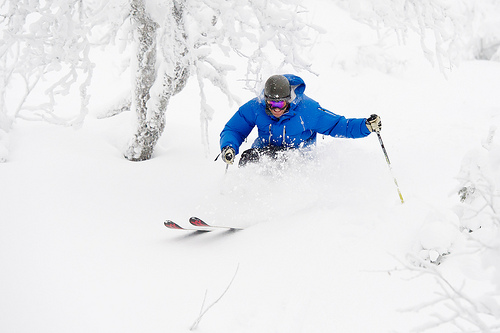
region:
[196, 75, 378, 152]
the blue snow jacket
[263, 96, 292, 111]
the iridescent snow goggles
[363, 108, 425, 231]
the left ski pole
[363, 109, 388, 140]
the gloves on the left hand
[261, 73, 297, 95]
the hat of the skier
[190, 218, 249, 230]
the left ski of the skier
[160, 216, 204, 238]
the right ski of the skier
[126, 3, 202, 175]
the snow covered tree trunk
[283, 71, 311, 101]
the hood of the blue jacket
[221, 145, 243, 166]
the right glove of the skier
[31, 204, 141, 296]
ground covered in white snow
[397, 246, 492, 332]
tree branches covered in snow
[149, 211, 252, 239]
red and black skis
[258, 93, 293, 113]
pair of purple safety goggles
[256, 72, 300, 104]
black safety helmet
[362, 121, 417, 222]
black and yellow ski pole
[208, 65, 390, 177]
man in blue jacket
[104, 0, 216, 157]
tree covered in snow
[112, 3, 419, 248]
man skiing in snow covered forest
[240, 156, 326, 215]
snow cloud flying in air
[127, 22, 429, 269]
a person skiing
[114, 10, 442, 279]
a person in blue snow coat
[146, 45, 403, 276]
a person in blue coat skiing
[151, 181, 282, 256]
a partially seen skis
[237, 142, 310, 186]
a partially visible black pants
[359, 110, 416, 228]
a ski pole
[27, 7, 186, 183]
trees covered with snow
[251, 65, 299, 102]
a black helmet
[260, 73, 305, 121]
a person wearing a google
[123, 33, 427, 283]
a skier in motion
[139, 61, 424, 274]
a person skiing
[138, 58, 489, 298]
a person skiingin snow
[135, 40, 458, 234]
a person surround by snow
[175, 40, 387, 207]
a person wearing a helmet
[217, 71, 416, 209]
a person wearing a black helmet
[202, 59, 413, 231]
a person wearing a jacket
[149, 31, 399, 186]
a person wearing a blue jacket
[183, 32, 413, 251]
a person holding ski poles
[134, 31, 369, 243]
a person on skies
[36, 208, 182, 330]
ground covered in snow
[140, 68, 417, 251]
a man riding skis down a snow covered slope.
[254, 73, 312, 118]
a man wearing a helmet.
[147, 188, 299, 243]
skis flying through snow.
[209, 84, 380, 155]
a blue puffy jacket.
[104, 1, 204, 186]
a tree covered in snow.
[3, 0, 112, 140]
snow covered tree branches.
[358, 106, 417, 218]
a ski pole in snow.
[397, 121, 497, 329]
snow drenched tree branches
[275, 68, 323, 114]
a hood on a jacket.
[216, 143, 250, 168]
a glove on a left hand.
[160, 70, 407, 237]
man skiing in blue snow coat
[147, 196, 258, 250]
red and black skis